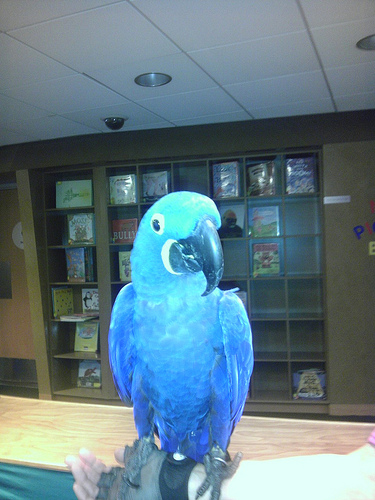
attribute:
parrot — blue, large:
[118, 203, 238, 415]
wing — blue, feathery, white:
[102, 297, 149, 400]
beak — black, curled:
[187, 228, 234, 299]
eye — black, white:
[150, 213, 162, 235]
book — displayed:
[54, 179, 97, 204]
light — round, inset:
[132, 67, 173, 99]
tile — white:
[16, 24, 320, 147]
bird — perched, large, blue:
[105, 184, 260, 407]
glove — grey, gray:
[111, 433, 196, 500]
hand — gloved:
[66, 426, 162, 498]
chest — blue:
[145, 307, 201, 340]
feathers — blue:
[238, 340, 262, 392]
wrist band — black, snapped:
[159, 457, 204, 498]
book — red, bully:
[111, 220, 145, 248]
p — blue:
[350, 220, 362, 245]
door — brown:
[1, 187, 31, 401]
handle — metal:
[1, 259, 13, 309]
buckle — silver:
[166, 448, 202, 471]